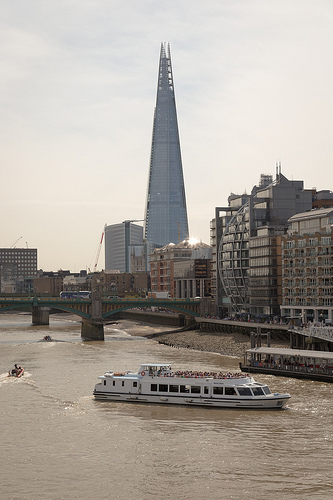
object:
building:
[142, 41, 188, 271]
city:
[0, 41, 331, 500]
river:
[0, 317, 332, 500]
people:
[218, 371, 242, 379]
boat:
[7, 364, 24, 378]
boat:
[42, 335, 52, 341]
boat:
[239, 346, 333, 382]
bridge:
[0, 297, 201, 340]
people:
[14, 363, 21, 369]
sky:
[0, 0, 333, 214]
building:
[147, 243, 192, 291]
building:
[279, 207, 333, 325]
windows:
[321, 237, 331, 245]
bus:
[60, 291, 92, 299]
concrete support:
[81, 319, 104, 341]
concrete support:
[30, 307, 51, 325]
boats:
[92, 363, 291, 408]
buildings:
[0, 247, 37, 293]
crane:
[92, 223, 107, 273]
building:
[104, 221, 143, 274]